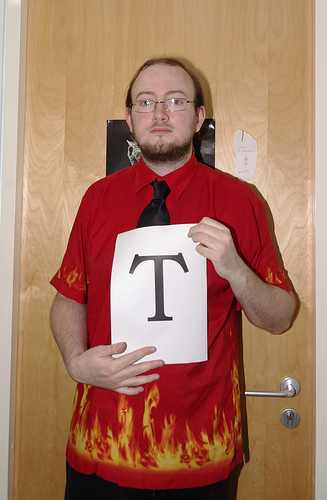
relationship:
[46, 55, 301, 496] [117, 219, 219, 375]
man holding paper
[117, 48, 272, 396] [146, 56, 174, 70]
man has hair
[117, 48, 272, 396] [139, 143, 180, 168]
man has hair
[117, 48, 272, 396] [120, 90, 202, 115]
man wearing glasses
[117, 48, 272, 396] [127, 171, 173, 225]
man wearing tie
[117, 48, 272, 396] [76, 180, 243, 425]
man wering shirt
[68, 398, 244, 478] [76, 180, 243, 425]
flames on shirt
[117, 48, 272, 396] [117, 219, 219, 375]
man holding paper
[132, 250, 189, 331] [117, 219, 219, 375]
t on paper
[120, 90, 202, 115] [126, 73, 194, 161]
glasses on face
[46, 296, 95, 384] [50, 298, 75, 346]
arm has hair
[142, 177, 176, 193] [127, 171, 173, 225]
knot on tie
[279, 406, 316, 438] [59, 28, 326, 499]
lock on door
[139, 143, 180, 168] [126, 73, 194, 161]
hair on face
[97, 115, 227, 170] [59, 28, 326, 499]
poster on door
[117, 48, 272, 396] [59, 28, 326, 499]
man by door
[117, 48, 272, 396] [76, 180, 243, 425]
man wearing shirt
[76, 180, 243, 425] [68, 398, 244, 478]
shirt has flames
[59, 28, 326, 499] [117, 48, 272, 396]
door behind man